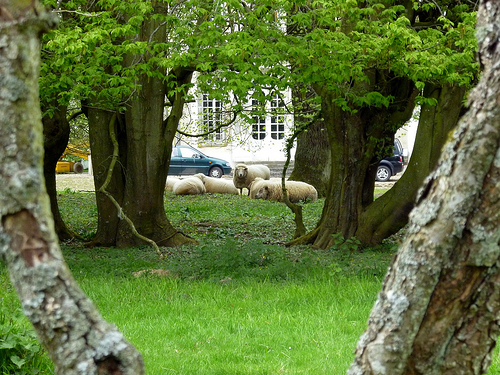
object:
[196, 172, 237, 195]
sheep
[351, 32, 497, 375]
tree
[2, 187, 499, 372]
grass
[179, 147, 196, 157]
car window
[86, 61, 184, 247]
trunk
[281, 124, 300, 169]
skinny tree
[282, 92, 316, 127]
leaves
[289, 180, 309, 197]
wool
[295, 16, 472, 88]
leaves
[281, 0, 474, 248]
tree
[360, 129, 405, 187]
car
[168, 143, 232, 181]
car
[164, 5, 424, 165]
building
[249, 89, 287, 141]
window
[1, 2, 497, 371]
park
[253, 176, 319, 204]
sheep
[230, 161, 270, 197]
sheep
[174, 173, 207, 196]
sheep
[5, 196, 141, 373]
tree